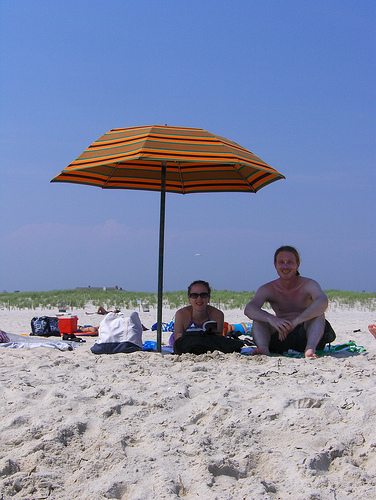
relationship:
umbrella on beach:
[49, 122, 286, 354] [4, 292, 364, 497]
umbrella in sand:
[49, 122, 286, 354] [23, 337, 361, 490]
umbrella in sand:
[49, 122, 286, 350] [0, 307, 363, 498]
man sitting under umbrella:
[244, 245, 329, 358] [49, 122, 286, 354]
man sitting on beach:
[244, 245, 329, 358] [4, 292, 364, 497]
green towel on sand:
[331, 335, 362, 360] [323, 350, 363, 383]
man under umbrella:
[244, 245, 329, 358] [47, 110, 299, 212]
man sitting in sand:
[244, 245, 329, 358] [0, 307, 363, 498]